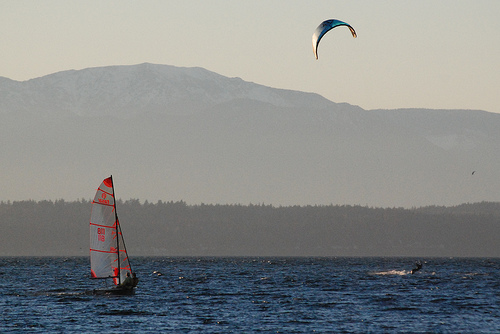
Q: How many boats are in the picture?
A: One.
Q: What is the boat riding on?
A: Water.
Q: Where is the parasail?
A: In the sky.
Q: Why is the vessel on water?
A: It's a boat.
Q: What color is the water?
A: Blue.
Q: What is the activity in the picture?
A: Sailing.